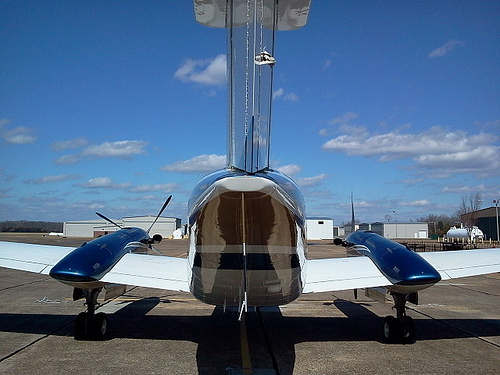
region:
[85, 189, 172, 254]
thin black plane propeller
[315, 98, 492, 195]
grey and white clouds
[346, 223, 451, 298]
metallic blue jet engine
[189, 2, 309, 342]
silver and metallic blue tail of jet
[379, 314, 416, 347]
landing wheels on jet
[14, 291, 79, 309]
words spray-painted on ground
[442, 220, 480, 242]
white tank behind tree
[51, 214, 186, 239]
grey building on tarmac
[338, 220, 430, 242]
grey building with white rolling door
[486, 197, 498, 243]
grey speakers on pole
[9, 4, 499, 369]
back view of a parked plane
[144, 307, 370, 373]
shadow on the ground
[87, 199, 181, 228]
propeller of a plane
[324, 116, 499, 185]
clouds in the sky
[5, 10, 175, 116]
blue sky in the background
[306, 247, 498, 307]
right wing of a plane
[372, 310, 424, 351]
wheels of a plane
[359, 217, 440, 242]
buildings in the background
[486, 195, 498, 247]
street lights on a pole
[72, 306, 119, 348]
left wheels of a plane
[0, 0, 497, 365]
A plane on the tarmac.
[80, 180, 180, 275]
A propeller on the plane.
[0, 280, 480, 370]
The shadow of a plane.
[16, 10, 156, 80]
Part of the sky is blue.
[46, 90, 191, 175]
Clouds in the blue sky.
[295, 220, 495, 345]
A wing on the airplane.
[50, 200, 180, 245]
A building in the distance.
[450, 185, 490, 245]
A tree next to a building.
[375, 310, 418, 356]
A wheel on the airplane.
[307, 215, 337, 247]
The Building in the distance is white.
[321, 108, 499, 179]
cloud formation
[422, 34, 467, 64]
small wisp of a white cloud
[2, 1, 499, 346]
plane sitting on the tarmac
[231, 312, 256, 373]
yellow line painted on the ground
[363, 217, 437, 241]
gray building with a bright white door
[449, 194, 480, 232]
skinny tree with no leaves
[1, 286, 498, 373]
shadow of the plane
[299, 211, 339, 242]
white building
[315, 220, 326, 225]
small black rectangle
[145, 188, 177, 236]
long, thin propeller blade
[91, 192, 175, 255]
the black propeller of a plane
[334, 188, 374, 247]
the black propeller of a plane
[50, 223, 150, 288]
the blue portion of a plane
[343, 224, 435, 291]
the blue portion of a plane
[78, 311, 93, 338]
the wheel of a plane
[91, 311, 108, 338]
the wheel of a plane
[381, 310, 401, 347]
the wheel of a plane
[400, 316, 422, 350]
the wheel of a plane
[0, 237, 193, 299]
the wing of the plane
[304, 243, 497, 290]
the wing of the plane